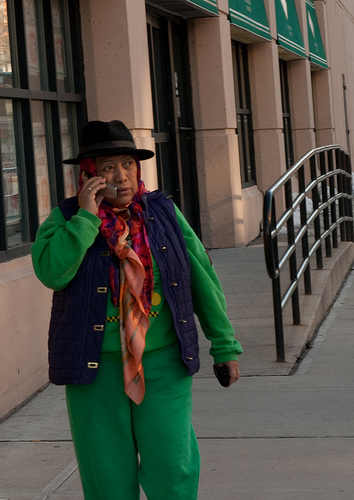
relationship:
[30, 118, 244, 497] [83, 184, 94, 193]
woman wearing a ring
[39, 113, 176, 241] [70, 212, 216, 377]
woman wearing a shirt